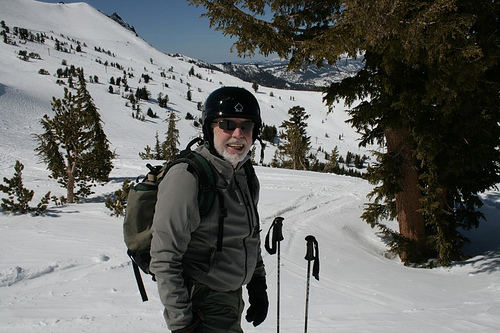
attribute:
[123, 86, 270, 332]
man — posing, looking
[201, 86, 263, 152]
helmet — black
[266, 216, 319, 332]
ski poles — black, stuck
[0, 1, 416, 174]
mountain — here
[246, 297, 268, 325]
glove — black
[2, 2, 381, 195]
trees — small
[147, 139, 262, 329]
jacket — gray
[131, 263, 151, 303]
strap — black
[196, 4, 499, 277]
tree — shadowed